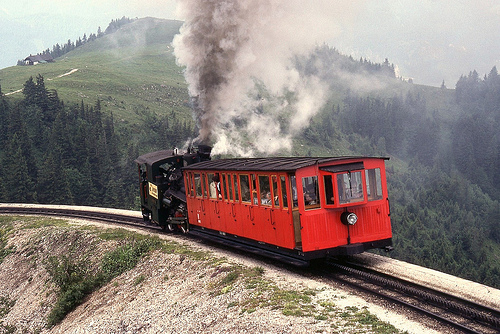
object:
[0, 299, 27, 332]
short grass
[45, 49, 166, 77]
green grass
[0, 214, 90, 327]
brown grass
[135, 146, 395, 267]
train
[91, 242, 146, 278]
brown grass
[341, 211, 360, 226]
light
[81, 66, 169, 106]
grass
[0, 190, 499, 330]
track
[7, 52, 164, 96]
road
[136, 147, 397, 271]
car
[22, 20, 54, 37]
clouds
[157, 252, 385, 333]
grass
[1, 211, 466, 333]
slope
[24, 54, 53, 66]
house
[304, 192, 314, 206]
person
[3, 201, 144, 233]
curved track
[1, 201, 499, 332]
railroad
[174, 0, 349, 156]
smoke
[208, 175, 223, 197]
passengers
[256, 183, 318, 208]
passengers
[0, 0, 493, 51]
sky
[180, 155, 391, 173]
roof